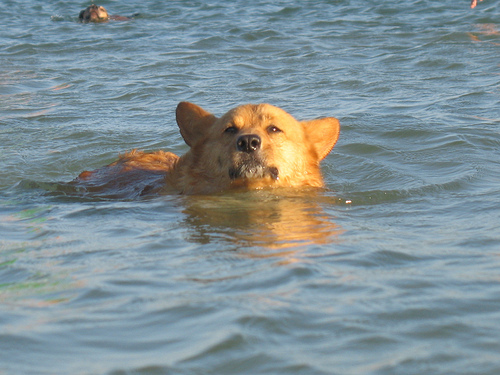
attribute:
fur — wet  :
[292, 143, 309, 187]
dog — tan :
[107, 100, 343, 213]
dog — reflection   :
[93, 98, 350, 231]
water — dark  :
[66, 225, 433, 344]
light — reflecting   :
[278, 150, 323, 243]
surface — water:
[172, 197, 357, 249]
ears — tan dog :
[301, 112, 346, 161]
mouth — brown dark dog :
[227, 157, 286, 177]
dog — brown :
[58, 90, 330, 244]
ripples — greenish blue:
[259, 252, 402, 340]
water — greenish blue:
[176, 294, 376, 364]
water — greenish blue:
[144, 224, 389, 338]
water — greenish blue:
[203, 290, 448, 373]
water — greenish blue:
[248, 236, 429, 369]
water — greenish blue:
[326, 278, 441, 368]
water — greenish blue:
[322, 282, 462, 359]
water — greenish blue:
[368, 278, 453, 370]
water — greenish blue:
[178, 289, 409, 355]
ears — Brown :
[308, 108, 348, 165]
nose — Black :
[241, 130, 265, 160]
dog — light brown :
[66, 96, 346, 197]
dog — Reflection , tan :
[34, 100, 357, 208]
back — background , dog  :
[115, 142, 186, 178]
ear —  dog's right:
[306, 109, 343, 159]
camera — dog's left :
[148, 88, 388, 335]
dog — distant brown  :
[53, 94, 342, 240]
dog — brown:
[88, 84, 353, 202]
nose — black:
[234, 131, 265, 155]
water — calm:
[76, 260, 466, 360]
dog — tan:
[46, 90, 359, 201]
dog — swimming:
[57, 100, 346, 214]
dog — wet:
[43, 74, 350, 215]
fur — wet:
[154, 156, 216, 201]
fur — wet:
[108, 150, 208, 220]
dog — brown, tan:
[74, 6, 114, 26]